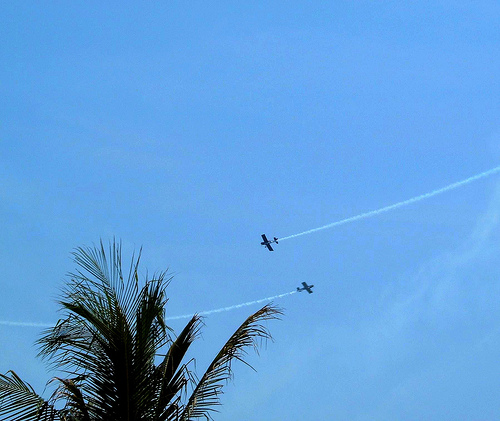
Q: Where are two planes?
A: In the sky.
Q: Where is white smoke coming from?
A: The planes.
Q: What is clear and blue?
A: The sky.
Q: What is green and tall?
A: A tree.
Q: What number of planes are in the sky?
A: Two.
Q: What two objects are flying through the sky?
A: Two planes.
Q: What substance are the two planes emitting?
A: Smoke.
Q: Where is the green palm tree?
A: To the bottom left.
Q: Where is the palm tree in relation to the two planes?
A: To the bottom left.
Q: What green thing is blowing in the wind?
A: A palm tree.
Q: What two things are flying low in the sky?
A: Two planes.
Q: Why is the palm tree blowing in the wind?
A: Because the wind is blowing.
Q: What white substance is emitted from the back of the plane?
A: Smoke.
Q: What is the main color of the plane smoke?
A: White.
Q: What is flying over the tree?
A: Planes.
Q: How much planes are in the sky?
A: Two.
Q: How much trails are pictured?
A: Two.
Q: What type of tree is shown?
A: A palm tree.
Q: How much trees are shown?
A: One.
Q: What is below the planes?
A: A palm tree.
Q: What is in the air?
A: Two planes.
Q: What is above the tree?
A: The sky.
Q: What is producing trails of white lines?
A: Planes.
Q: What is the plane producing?
A: A white line.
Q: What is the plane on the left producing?
A: A white line.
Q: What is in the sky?
A: Planes.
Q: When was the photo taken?
A: Daytime.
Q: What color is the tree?
A: Green.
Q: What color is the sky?
A: Blue.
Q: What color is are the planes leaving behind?
A: White.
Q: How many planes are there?
A: Two.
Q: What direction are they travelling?
A: Opposite directions.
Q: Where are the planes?
A: In the sky.